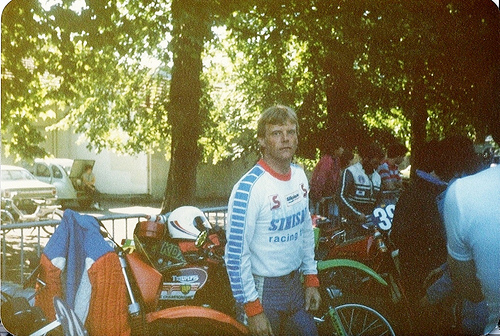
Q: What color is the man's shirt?
A: White.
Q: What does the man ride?
A: A dirt-style motorcycle.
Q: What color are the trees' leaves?
A: Green.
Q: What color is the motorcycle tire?
A: Black.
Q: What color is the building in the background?
A: Tan.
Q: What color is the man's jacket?
A: Red, white, and blue.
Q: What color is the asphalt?
A: Black.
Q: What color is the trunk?
A: Brown.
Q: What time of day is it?
A: Early afternoon.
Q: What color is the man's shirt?
A: White and blue.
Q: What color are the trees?
A: Green.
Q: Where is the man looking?
A: Looking at the photographer.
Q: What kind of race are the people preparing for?
A: Bike Race.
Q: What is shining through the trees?
A: Sunlight.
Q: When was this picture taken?
A: In the 70's.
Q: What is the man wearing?
A: A sweatshirt.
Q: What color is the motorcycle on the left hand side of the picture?
A: Red.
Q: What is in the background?
A: A group of trees.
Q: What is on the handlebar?
A: Jacket.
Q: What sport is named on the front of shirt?
A: Racing.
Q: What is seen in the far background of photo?
A: Trees.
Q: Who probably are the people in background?
A: Racers.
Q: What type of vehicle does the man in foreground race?
A: Motorcycle.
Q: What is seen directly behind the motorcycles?
A: Short barrier.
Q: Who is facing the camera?
A: A man.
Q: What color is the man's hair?
A: Blonde.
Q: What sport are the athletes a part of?
A: Racing.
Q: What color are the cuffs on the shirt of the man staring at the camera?
A: Orange.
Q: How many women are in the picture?
A: None.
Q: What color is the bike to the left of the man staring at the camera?
A: Orange and white.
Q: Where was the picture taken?
A: At a motocross event.